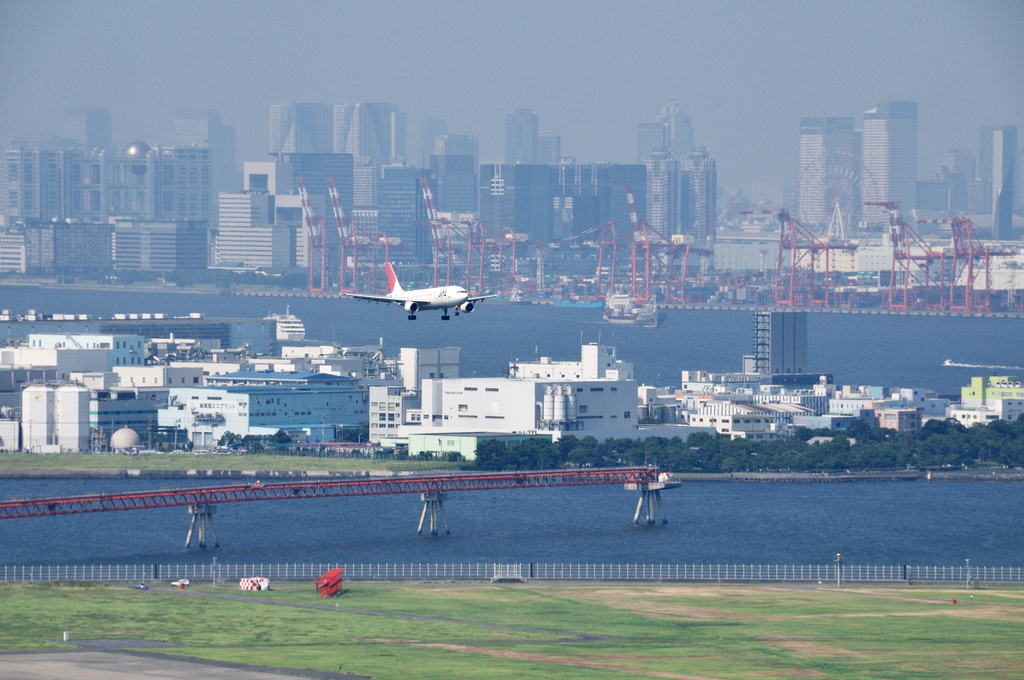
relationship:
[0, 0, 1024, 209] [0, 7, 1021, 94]
cloud in sky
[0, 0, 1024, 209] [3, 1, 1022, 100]
cloud in sky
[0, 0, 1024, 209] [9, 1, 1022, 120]
cloud in sky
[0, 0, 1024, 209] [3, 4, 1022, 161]
cloud in sky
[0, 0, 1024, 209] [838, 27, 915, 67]
cloud in sky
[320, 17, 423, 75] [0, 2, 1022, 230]
cloud in sky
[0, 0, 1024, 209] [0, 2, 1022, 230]
cloud in sky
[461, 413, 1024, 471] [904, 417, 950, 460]
leaves on tree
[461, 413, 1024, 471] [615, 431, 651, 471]
leaves on tree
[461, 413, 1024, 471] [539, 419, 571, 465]
leaves on tree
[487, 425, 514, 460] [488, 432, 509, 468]
leaves on tree